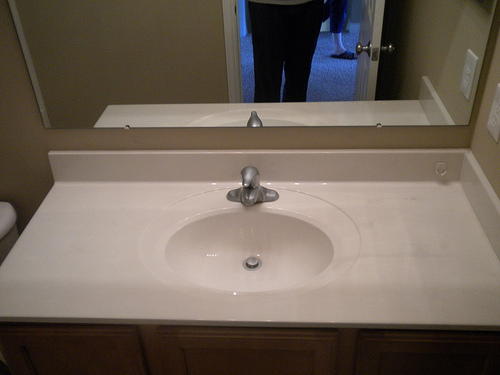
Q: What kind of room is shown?
A: It is a bathroom.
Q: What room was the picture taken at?
A: It was taken at the bathroom.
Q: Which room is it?
A: It is a bathroom.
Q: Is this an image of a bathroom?
A: Yes, it is showing a bathroom.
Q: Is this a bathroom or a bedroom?
A: It is a bathroom.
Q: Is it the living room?
A: No, it is the bathroom.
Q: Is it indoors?
A: Yes, it is indoors.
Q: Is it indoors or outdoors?
A: It is indoors.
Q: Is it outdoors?
A: No, it is indoors.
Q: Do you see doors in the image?
A: Yes, there is a door.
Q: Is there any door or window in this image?
A: Yes, there is a door.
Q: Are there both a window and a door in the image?
A: No, there is a door but no windows.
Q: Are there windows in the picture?
A: No, there are no windows.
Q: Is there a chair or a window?
A: No, there are no windows or chairs.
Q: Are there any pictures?
A: No, there are no pictures.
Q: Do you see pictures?
A: No, there are no pictures.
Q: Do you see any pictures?
A: No, there are no pictures.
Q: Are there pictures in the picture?
A: No, there are no pictures.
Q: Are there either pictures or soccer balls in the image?
A: No, there are no pictures or soccer balls.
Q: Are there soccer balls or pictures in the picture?
A: No, there are no pictures or soccer balls.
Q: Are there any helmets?
A: No, there are no helmets.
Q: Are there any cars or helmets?
A: No, there are no helmets or cars.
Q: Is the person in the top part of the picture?
A: Yes, the person is in the top of the image.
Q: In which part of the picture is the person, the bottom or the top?
A: The person is in the top of the image.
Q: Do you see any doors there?
A: Yes, there is a door.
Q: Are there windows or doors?
A: Yes, there is a door.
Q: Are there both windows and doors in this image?
A: No, there is a door but no windows.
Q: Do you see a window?
A: No, there are no windows.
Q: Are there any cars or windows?
A: No, there are no windows or cars.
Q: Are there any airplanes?
A: Yes, there is an airplane.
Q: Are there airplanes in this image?
A: Yes, there is an airplane.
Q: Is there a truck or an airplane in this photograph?
A: Yes, there is an airplane.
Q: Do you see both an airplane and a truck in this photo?
A: No, there is an airplane but no trucks.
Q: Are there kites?
A: No, there are no kites.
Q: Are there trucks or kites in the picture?
A: No, there are no kites or trucks.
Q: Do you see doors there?
A: Yes, there is a door.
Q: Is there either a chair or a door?
A: Yes, there is a door.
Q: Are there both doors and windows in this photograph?
A: No, there is a door but no windows.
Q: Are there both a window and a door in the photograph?
A: No, there is a door but no windows.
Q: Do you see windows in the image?
A: No, there are no windows.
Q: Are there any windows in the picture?
A: No, there are no windows.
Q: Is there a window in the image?
A: No, there are no windows.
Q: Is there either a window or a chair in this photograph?
A: No, there are no windows or chairs.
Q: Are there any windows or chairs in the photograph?
A: No, there are no windows or chairs.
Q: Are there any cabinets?
A: Yes, there is a cabinet.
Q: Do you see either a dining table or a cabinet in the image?
A: Yes, there is a cabinet.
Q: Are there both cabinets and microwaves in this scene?
A: No, there is a cabinet but no microwaves.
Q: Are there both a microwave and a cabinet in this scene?
A: No, there is a cabinet but no microwaves.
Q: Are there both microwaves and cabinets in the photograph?
A: No, there is a cabinet but no microwaves.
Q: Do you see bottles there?
A: No, there are no bottles.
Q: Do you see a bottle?
A: No, there are no bottles.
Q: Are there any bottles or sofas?
A: No, there are no bottles or sofas.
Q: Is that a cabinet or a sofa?
A: That is a cabinet.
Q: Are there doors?
A: Yes, there is a door.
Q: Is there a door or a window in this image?
A: Yes, there is a door.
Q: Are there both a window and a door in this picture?
A: No, there is a door but no windows.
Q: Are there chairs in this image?
A: No, there are no chairs.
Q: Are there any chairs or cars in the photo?
A: No, there are no chairs or cars.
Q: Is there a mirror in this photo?
A: Yes, there is a mirror.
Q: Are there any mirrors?
A: Yes, there is a mirror.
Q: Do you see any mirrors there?
A: Yes, there is a mirror.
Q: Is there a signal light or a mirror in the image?
A: Yes, there is a mirror.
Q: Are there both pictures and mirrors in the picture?
A: No, there is a mirror but no pictures.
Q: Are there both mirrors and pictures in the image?
A: No, there is a mirror but no pictures.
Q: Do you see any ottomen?
A: No, there are no ottomen.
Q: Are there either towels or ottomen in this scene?
A: No, there are no ottomen or towels.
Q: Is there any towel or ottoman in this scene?
A: No, there are no ottomen or towels.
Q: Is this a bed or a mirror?
A: This is a mirror.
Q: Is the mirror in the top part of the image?
A: Yes, the mirror is in the top of the image.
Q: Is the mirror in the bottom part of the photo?
A: No, the mirror is in the top of the image.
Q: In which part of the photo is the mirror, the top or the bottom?
A: The mirror is in the top of the image.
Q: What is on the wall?
A: The mirror is on the wall.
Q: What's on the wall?
A: The mirror is on the wall.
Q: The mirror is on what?
A: The mirror is on the wall.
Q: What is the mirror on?
A: The mirror is on the wall.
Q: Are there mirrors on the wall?
A: Yes, there is a mirror on the wall.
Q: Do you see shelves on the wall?
A: No, there is a mirror on the wall.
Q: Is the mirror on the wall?
A: Yes, the mirror is on the wall.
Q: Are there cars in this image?
A: No, there are no cars.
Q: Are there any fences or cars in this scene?
A: No, there are no cars or fences.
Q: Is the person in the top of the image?
A: Yes, the person is in the top of the image.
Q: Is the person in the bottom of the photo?
A: No, the person is in the top of the image.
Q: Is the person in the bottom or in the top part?
A: The person is in the top of the image.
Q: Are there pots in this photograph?
A: No, there are no pots.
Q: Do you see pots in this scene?
A: No, there are no pots.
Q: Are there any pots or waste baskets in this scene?
A: No, there are no pots or waste baskets.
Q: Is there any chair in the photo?
A: No, there are no chairs.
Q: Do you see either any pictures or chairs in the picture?
A: No, there are no chairs or pictures.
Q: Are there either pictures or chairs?
A: No, there are no chairs or pictures.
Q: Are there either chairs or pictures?
A: No, there are no chairs or pictures.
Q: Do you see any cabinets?
A: Yes, there is a cabinet.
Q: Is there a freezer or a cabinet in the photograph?
A: Yes, there is a cabinet.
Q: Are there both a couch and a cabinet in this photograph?
A: No, there is a cabinet but no couches.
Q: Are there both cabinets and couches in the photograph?
A: No, there is a cabinet but no couches.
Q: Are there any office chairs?
A: No, there are no office chairs.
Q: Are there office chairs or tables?
A: No, there are no office chairs or tables.